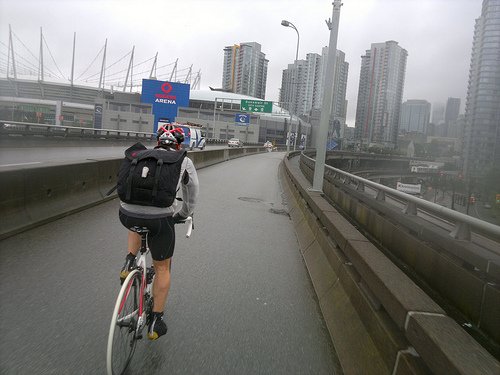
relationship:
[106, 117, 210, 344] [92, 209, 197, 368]
bicyclist riding bicycle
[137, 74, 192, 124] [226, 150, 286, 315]
sign by road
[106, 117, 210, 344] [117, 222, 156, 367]
bicyclist riding bike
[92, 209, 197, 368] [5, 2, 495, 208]
bicycle in downtown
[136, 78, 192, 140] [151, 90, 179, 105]
blue billboard has lettering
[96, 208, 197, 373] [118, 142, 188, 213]
bicyclist has shirt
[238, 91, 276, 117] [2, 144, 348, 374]
sign over path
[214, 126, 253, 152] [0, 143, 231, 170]
car on street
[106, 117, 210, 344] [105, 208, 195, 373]
bicyclist on bike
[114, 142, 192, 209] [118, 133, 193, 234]
backpack on man's back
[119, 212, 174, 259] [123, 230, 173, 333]
shorts on legs